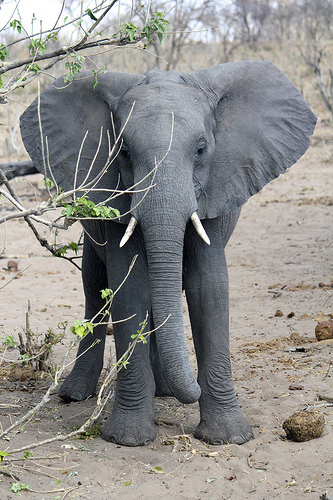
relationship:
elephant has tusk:
[18, 59, 317, 447] [190, 211, 215, 247]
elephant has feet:
[18, 59, 317, 447] [59, 375, 253, 447]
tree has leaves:
[1, 0, 218, 488] [1, 8, 172, 468]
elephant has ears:
[18, 59, 317, 447] [20, 60, 318, 226]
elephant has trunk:
[18, 59, 317, 447] [140, 213, 203, 404]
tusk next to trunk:
[190, 211, 215, 247] [140, 213, 203, 404]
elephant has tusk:
[18, 59, 317, 447] [118, 216, 137, 249]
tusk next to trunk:
[118, 216, 137, 249] [140, 213, 203, 404]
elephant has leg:
[18, 59, 317, 447] [190, 248, 256, 446]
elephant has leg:
[18, 59, 317, 447] [102, 224, 159, 445]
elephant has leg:
[18, 59, 317, 447] [149, 314, 178, 398]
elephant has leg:
[18, 59, 317, 447] [59, 238, 111, 402]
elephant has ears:
[18, 59, 317, 447] [199, 60, 318, 226]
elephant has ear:
[18, 59, 317, 447] [18, 69, 138, 226]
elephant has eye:
[18, 59, 317, 447] [194, 140, 208, 156]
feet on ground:
[59, 375, 253, 447] [1, 109, 333, 499]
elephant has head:
[18, 59, 317, 447] [110, 82, 218, 228]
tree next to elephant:
[1, 0, 218, 488] [18, 59, 317, 447]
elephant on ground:
[18, 59, 317, 447] [1, 109, 333, 499]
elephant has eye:
[18, 59, 317, 447] [116, 141, 131, 155]